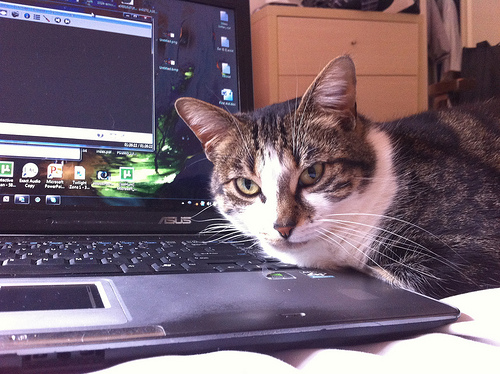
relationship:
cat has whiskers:
[175, 53, 495, 296] [211, 84, 317, 163]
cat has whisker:
[175, 53, 495, 296] [192, 201, 215, 217]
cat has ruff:
[175, 53, 495, 296] [260, 128, 400, 273]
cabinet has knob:
[244, 5, 427, 127] [347, 37, 362, 48]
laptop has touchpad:
[0, 0, 461, 372] [0, 276, 102, 318]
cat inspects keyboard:
[175, 53, 495, 296] [0, 230, 291, 281]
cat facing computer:
[175, 53, 495, 296] [0, 0, 461, 372]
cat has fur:
[175, 53, 495, 296] [367, 93, 500, 296]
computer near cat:
[0, 0, 461, 372] [175, 53, 495, 296]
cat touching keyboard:
[175, 53, 495, 296] [0, 230, 291, 281]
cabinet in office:
[244, 5, 427, 127] [250, 3, 498, 148]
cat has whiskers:
[175, 53, 495, 296] [195, 216, 467, 281]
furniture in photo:
[244, 5, 427, 127] [1, 1, 500, 372]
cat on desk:
[175, 53, 495, 296] [3, 281, 500, 371]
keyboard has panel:
[0, 230, 291, 281] [2, 263, 453, 341]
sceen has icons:
[0, 4, 236, 215] [215, 9, 237, 113]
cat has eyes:
[175, 53, 495, 296] [230, 158, 330, 204]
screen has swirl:
[0, 4, 236, 215] [80, 82, 194, 199]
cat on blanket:
[175, 53, 495, 296] [1, 282, 498, 373]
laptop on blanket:
[0, 0, 461, 372] [1, 282, 498, 373]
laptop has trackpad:
[0, 0, 461, 372] [0, 276, 102, 318]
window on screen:
[1, 1, 165, 150] [0, 4, 236, 215]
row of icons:
[211, 7, 245, 113] [215, 9, 237, 113]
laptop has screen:
[0, 0, 461, 372] [0, 4, 236, 215]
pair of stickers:
[163, 57, 173, 60] [170, 63, 173, 64]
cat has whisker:
[175, 53, 495, 296] [322, 210, 483, 275]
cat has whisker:
[175, 53, 495, 296] [324, 219, 481, 291]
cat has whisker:
[175, 53, 495, 296] [313, 226, 388, 285]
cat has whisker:
[175, 53, 495, 296] [236, 240, 259, 253]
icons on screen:
[215, 9, 237, 113] [0, 4, 236, 215]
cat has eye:
[175, 53, 495, 296] [299, 159, 326, 188]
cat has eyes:
[175, 53, 495, 296] [230, 171, 265, 205]